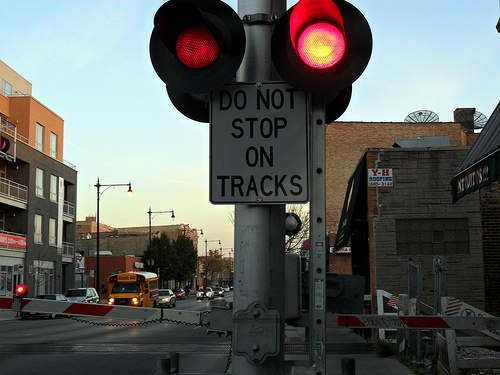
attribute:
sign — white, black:
[198, 80, 325, 205]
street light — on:
[85, 162, 145, 207]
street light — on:
[139, 194, 189, 239]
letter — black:
[273, 115, 286, 139]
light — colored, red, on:
[287, 0, 348, 72]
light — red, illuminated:
[268, 6, 351, 73]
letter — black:
[288, 84, 300, 110]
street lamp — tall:
[90, 175, 137, 290]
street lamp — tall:
[140, 209, 182, 265]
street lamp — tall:
[177, 227, 209, 239]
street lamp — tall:
[201, 235, 223, 274]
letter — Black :
[228, 114, 247, 141]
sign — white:
[367, 166, 393, 186]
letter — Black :
[252, 85, 272, 116]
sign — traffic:
[210, 86, 308, 207]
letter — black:
[214, 87, 235, 114]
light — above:
[119, 177, 144, 207]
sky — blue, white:
[2, 2, 499, 258]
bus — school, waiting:
[106, 267, 159, 314]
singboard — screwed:
[202, 80, 309, 205]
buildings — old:
[335, 144, 482, 350]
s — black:
[227, 117, 247, 144]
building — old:
[293, 106, 490, 292]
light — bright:
[291, 17, 350, 71]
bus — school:
[104, 264, 174, 311]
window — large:
[32, 123, 47, 155]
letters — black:
[215, 93, 302, 200]